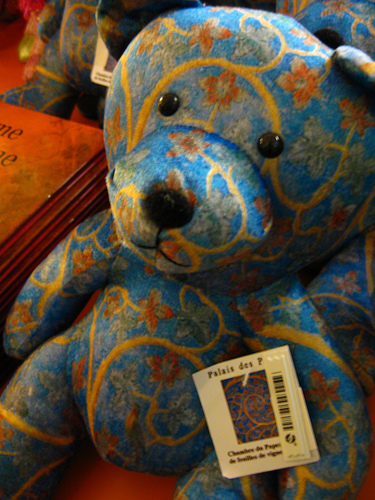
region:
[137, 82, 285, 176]
teddy bear's eyes are black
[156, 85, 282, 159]
teddy bear's eyes are black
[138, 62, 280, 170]
teddy bear's eyes are black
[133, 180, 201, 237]
the nose is black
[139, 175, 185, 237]
the nose is black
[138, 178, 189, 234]
the nose is black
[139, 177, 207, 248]
the nose is black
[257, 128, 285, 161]
left black eye on a teddy bear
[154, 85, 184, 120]
right black eye on a teddy bear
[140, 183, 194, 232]
black nose on a teddy bear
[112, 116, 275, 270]
snout of a teddy bear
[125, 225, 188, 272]
mouth of a teddy bear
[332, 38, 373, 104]
left ear of a teddy bear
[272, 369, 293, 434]
bar code on a tag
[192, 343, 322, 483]
tag on a teddy bear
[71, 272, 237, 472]
body of a teddy bear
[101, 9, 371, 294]
head of a teddy bear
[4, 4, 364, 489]
blue fabric bear with swirling yellow print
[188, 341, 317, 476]
tag and bar code attached to bear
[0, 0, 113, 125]
part of tag and part of bear in background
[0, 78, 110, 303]
brown book with letters on cover in a stack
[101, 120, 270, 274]
oval snout with black nose and mouth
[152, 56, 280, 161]
orange flower between two black eyes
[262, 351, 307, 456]
thin and thick black lines across tag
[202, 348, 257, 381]
words written in a language that is not English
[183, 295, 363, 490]
tag showing the same pattern as is on the bear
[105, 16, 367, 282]
light falling over top of head and snout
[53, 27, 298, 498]
teddy bear's print is flowers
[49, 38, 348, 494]
teddy bear's print is flowers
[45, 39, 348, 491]
teddy bear's print is flowers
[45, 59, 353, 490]
teddy bear's print is flowers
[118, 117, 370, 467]
teddy bear's print is flowers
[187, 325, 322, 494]
tag attached to teddy bear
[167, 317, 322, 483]
tag attached to teddy bear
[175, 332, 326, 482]
tag attached to teddy bear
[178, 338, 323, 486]
tag attached to teddy bear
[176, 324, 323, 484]
tag attached to teddy bear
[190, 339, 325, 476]
tag on a teddy bear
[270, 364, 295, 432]
bar code on a tag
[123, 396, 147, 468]
bird on the teddy bear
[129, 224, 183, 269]
black mouth on a teddy bear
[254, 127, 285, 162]
teddy bear's left eye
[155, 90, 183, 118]
teddy bear's right eye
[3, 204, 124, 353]
right arm of a teddy bear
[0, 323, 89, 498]
right leg of a teddy bear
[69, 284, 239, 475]
belly of a teddy bear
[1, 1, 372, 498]
stuffed toy bear with tag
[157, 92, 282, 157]
two black plastic eyes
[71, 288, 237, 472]
design on toy body